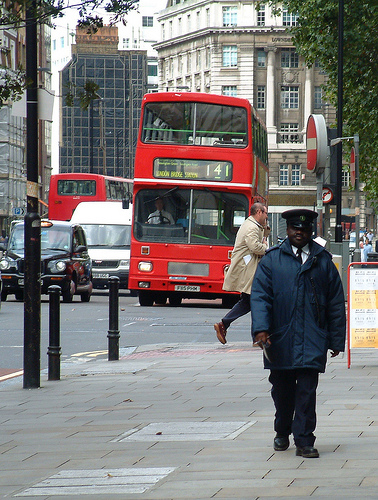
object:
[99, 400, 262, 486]
sidewalk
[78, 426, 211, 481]
sidewalk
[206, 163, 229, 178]
number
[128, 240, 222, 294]
bottom deck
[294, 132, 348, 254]
pole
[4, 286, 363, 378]
street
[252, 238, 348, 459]
uniform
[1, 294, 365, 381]
road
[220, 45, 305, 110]
window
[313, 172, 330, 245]
pole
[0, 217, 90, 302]
car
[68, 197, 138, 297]
car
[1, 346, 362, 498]
sidewalk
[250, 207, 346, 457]
outfit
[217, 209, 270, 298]
coat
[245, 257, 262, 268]
pocket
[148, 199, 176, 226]
driver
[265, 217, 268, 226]
phone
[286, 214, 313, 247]
head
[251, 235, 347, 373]
coat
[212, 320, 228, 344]
shoe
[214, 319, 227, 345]
foot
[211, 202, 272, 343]
man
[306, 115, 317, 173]
edge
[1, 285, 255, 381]
street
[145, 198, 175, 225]
man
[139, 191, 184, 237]
driver's seat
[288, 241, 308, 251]
neck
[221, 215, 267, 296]
jacket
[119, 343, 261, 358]
tile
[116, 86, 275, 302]
windshield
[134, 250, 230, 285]
headlight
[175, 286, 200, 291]
plate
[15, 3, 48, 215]
pole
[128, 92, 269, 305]
bus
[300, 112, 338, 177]
sign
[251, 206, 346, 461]
man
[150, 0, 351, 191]
building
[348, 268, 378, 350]
advertisement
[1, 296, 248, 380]
road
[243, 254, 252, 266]
paper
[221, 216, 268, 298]
coat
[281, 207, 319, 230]
hat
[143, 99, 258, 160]
window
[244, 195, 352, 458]
policeman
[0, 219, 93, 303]
bentley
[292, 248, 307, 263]
tie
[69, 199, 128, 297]
van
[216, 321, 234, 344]
shoes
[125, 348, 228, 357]
tiles